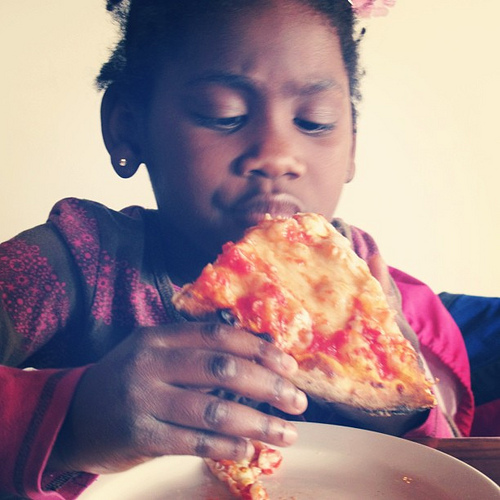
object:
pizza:
[172, 210, 434, 437]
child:
[0, 0, 500, 500]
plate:
[61, 421, 498, 499]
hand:
[68, 323, 309, 477]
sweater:
[0, 197, 475, 500]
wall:
[0, 0, 499, 297]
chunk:
[203, 435, 282, 499]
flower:
[10, 259, 25, 272]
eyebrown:
[183, 149, 255, 165]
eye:
[200, 110, 246, 128]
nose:
[237, 111, 305, 180]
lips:
[227, 194, 307, 232]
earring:
[118, 158, 127, 166]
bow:
[347, 0, 398, 20]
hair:
[94, 0, 367, 136]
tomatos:
[311, 328, 338, 353]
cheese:
[170, 208, 438, 402]